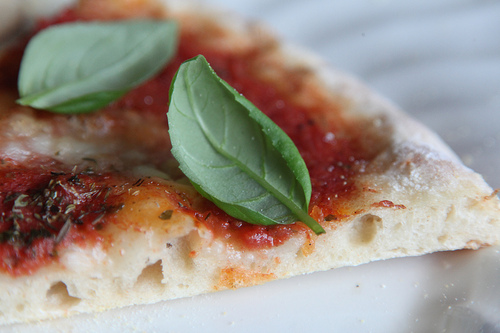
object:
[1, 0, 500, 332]
plate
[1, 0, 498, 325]
crust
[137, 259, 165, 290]
bubble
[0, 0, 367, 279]
sauce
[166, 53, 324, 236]
leaf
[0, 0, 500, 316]
pizza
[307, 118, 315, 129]
pepper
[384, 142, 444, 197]
flour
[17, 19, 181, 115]
leaf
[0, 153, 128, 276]
dry herb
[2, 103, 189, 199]
cheese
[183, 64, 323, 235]
stem